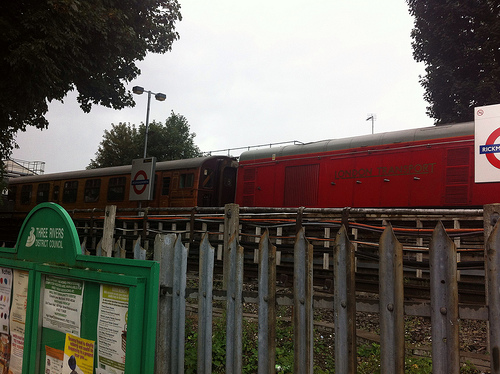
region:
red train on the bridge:
[210, 145, 467, 195]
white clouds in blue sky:
[192, 15, 243, 62]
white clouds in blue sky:
[37, 122, 79, 163]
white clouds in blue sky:
[171, 55, 242, 120]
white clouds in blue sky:
[225, 88, 277, 126]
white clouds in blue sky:
[237, 35, 269, 80]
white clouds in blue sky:
[270, 28, 330, 100]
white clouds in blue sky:
[282, 78, 333, 132]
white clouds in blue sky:
[320, 53, 362, 78]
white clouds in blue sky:
[261, 23, 349, 68]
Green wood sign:
[2, 200, 163, 371]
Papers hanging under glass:
[35, 274, 129, 372]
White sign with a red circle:
[470, 102, 498, 186]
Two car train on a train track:
[1, 103, 498, 290]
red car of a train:
[235, 115, 499, 260]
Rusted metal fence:
[91, 201, 497, 371]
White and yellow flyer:
[57, 330, 96, 372]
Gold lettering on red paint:
[330, 162, 434, 182]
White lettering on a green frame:
[21, 219, 66, 251]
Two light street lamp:
[132, 83, 167, 162]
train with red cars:
[1, 120, 496, 234]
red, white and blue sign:
[473, 101, 498, 185]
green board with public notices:
[1, 200, 162, 372]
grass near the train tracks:
[187, 305, 497, 372]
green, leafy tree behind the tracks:
[405, 0, 498, 125]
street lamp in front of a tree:
[126, 84, 167, 161]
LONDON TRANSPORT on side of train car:
[328, 159, 438, 181]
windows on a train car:
[8, 171, 197, 206]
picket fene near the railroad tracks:
[1, 201, 498, 372]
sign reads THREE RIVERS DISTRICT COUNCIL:
[23, 224, 68, 250]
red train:
[224, 151, 462, 199]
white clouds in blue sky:
[197, 11, 268, 83]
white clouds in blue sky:
[181, 56, 233, 94]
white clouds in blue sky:
[201, 82, 253, 132]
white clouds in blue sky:
[230, 13, 272, 50]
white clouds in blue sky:
[222, 46, 260, 87]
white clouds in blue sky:
[282, 46, 340, 106]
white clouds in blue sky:
[298, 19, 370, 67]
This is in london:
[65, 101, 492, 220]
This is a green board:
[26, 246, 203, 365]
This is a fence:
[193, 250, 279, 312]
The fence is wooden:
[157, 230, 422, 372]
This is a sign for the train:
[87, 121, 191, 204]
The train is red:
[203, 124, 450, 228]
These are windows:
[79, 156, 131, 206]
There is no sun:
[191, 76, 271, 128]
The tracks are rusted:
[229, 216, 416, 292]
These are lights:
[98, 63, 256, 131]